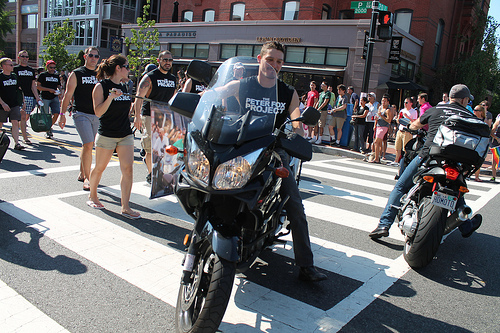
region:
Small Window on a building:
[281, 4, 313, 29]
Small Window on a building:
[322, 40, 356, 68]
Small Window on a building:
[301, 40, 328, 70]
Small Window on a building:
[280, 40, 310, 71]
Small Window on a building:
[220, 40, 241, 60]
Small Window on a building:
[179, 8, 206, 23]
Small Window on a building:
[198, 7, 218, 29]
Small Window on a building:
[228, 1, 250, 23]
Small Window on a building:
[387, 8, 417, 40]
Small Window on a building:
[428, 9, 446, 81]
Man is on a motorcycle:
[187, 39, 339, 289]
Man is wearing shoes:
[293, 262, 336, 282]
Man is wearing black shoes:
[290, 263, 329, 284]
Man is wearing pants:
[270, 136, 318, 271]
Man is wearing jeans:
[375, 148, 476, 237]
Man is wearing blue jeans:
[377, 147, 474, 237]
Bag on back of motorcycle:
[428, 109, 490, 170]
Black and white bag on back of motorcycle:
[425, 110, 492, 167]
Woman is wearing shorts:
[95, 126, 140, 153]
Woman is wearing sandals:
[84, 195, 141, 220]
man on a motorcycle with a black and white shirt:
[231, 41, 300, 132]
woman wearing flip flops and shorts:
[83, 54, 143, 219]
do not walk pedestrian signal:
[378, 10, 391, 40]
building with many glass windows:
[43, 1, 118, 52]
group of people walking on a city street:
[0, 42, 176, 237]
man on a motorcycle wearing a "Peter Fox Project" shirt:
[243, 40, 290, 150]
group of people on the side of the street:
[305, 75, 402, 155]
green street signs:
[348, 0, 388, 15]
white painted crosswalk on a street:
[2, 220, 167, 300]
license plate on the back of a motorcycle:
[430, 190, 459, 211]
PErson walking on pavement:
[90, 47, 145, 260]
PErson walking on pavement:
[55, 44, 107, 204]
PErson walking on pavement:
[360, 91, 402, 160]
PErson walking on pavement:
[35, 59, 73, 163]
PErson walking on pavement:
[8, 44, 56, 146]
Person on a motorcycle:
[162, 16, 289, 302]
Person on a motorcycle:
[365, 59, 465, 301]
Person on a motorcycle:
[303, 74, 338, 148]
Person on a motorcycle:
[319, 82, 351, 152]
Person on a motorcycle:
[332, 78, 361, 173]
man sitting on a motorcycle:
[166, 25, 337, 330]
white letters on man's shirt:
[225, 80, 290, 120]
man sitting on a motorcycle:
[357, 80, 488, 290]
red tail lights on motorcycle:
[403, 154, 475, 203]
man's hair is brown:
[247, 33, 295, 60]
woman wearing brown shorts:
[90, 122, 157, 163]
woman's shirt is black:
[81, 77, 141, 139]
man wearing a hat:
[433, 81, 480, 103]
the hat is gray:
[435, 72, 478, 110]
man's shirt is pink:
[411, 98, 433, 130]